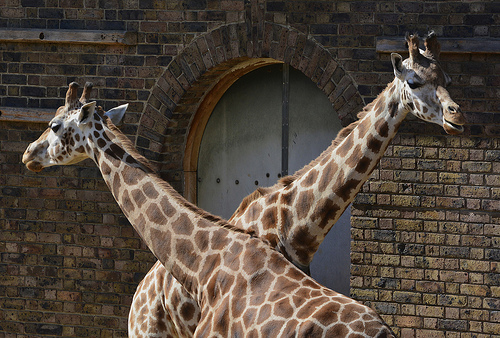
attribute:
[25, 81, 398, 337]
giraffe — spotted, standing, looking, brown, in front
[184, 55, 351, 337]
door — double door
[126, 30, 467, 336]
giraffe — standing, looking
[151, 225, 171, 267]
spot — brown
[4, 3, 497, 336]
building — brick, brown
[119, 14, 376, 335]
archway — brick, framed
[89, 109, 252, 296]
neck — long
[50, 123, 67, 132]
eye — pretty, large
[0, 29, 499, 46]
line — white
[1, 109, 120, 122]
line — white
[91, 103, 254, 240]
mane — short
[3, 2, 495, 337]
wall — brick, brown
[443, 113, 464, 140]
mouth — open